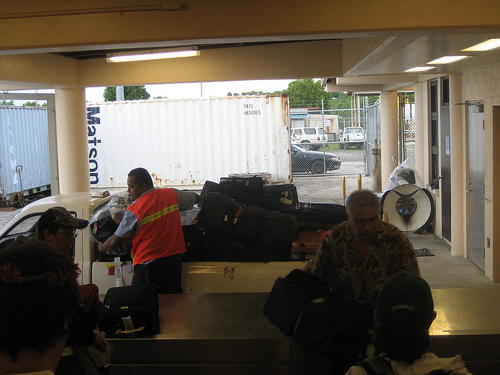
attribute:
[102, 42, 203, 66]
light — on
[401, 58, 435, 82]
light — on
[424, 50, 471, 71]
light — on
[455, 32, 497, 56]
light — on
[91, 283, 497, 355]
counter — gray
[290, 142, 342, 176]
car — black, parked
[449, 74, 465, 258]
pillar — white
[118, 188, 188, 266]
outfit — orange, yellow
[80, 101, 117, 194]
lettering — blue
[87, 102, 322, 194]
container — white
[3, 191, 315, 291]
truck — pickup truck, white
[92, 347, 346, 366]
counter — metallic, silver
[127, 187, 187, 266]
vest — orange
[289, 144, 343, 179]
car — black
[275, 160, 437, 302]
shirt — green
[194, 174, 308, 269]
luggage — black